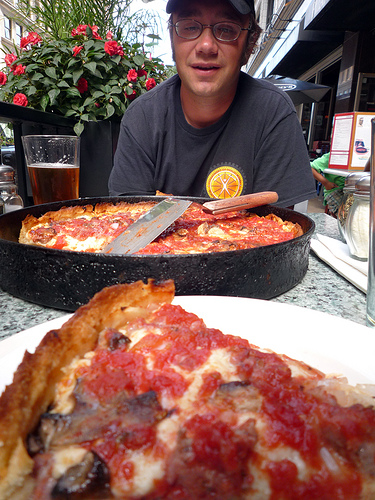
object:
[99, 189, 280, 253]
slicer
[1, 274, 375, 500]
slice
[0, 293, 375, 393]
plate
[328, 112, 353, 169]
menu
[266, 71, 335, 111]
shade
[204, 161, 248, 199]
logo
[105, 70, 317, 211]
shirt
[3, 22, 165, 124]
bush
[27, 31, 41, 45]
flowers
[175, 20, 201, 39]
eyeglass lens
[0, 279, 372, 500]
casserole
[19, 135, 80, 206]
glass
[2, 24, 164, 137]
carnations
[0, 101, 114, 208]
pot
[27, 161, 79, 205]
beer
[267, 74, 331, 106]
umbrella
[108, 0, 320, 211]
man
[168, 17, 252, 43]
glasses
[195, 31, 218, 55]
nose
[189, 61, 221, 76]
mouth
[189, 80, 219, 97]
chin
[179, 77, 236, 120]
neck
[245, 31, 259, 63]
ear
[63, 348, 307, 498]
cheese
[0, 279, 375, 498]
sauce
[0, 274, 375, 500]
pizza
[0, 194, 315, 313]
pan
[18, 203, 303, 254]
pizza